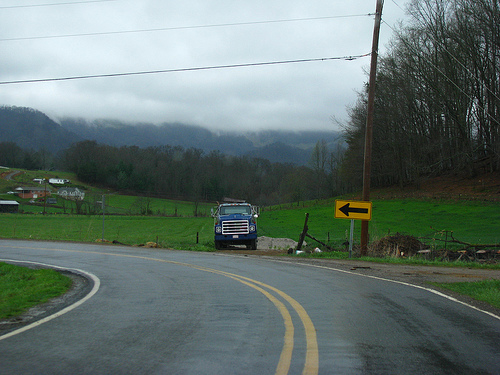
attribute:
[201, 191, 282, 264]
truck — driving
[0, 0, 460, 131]
sky — dull blue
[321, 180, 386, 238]
sign — yellow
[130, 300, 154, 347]
road — black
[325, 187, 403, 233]
sign — black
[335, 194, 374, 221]
pointer — yellow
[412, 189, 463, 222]
grass — fresh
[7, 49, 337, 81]
electrical line — black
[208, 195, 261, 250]
truck — blue 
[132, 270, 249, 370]
road — black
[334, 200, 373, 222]
sign — ROAD 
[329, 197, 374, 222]
sign — yellow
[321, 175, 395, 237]
sign — yellow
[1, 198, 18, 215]
houses — distant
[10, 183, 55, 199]
houses — distant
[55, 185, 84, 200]
houses — distant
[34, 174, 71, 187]
houses — distant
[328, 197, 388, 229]
sign — yellow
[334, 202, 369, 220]
arrow — black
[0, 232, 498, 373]
road — black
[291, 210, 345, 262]
fence — woodem posts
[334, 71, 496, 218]
trees — tall 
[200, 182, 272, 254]
truck — black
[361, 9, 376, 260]
pole — brown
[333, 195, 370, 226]
sign — yellow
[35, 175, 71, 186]
house — far  , hills  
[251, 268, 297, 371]
lines — yellow